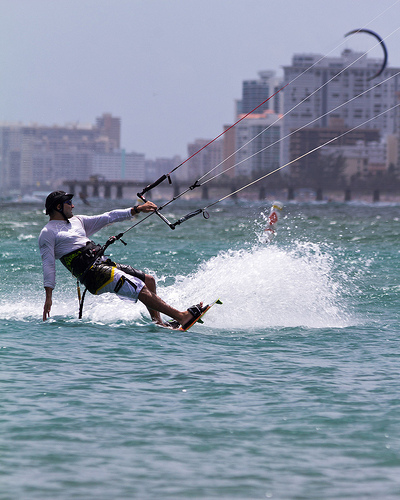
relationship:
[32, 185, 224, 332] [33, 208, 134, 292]
man wears shirt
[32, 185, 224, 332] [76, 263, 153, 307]
man wears shorts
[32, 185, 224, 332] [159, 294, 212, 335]
man wears slippers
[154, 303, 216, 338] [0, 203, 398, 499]
feet in water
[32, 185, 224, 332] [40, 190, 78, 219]
man wears hat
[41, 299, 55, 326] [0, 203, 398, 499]
hand in water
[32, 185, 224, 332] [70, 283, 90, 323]
man has strap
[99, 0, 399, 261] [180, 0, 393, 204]
kite has lines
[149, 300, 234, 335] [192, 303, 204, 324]
board has strap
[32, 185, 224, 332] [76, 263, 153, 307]
man wearing shorts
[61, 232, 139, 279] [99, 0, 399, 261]
belt gear attached to kite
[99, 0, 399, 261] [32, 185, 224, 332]
kite pulling man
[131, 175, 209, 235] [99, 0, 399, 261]
rods on kite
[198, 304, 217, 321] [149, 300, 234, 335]
tip of surfboard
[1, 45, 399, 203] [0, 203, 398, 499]
buildings next to lake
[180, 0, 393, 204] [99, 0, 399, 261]
lines on kite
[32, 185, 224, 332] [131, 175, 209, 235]
man holding rods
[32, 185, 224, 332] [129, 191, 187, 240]
man holding bar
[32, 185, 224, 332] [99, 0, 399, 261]
man holds kite